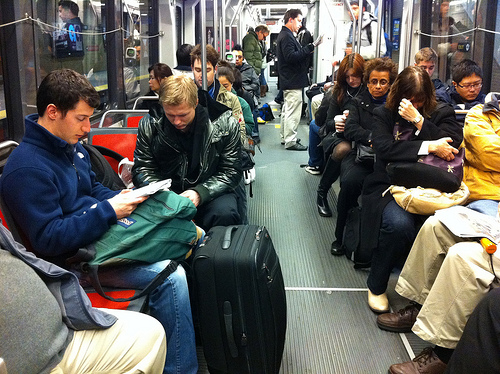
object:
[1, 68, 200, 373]
man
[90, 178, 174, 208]
paper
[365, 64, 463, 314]
person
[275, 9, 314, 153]
man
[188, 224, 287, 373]
suitcase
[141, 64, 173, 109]
woman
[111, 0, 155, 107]
window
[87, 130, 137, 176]
seat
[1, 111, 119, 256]
coat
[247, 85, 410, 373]
aisle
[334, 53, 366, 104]
hair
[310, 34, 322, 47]
paper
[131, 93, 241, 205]
jacket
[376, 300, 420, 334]
shoe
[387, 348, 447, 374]
shoe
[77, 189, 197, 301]
backpack